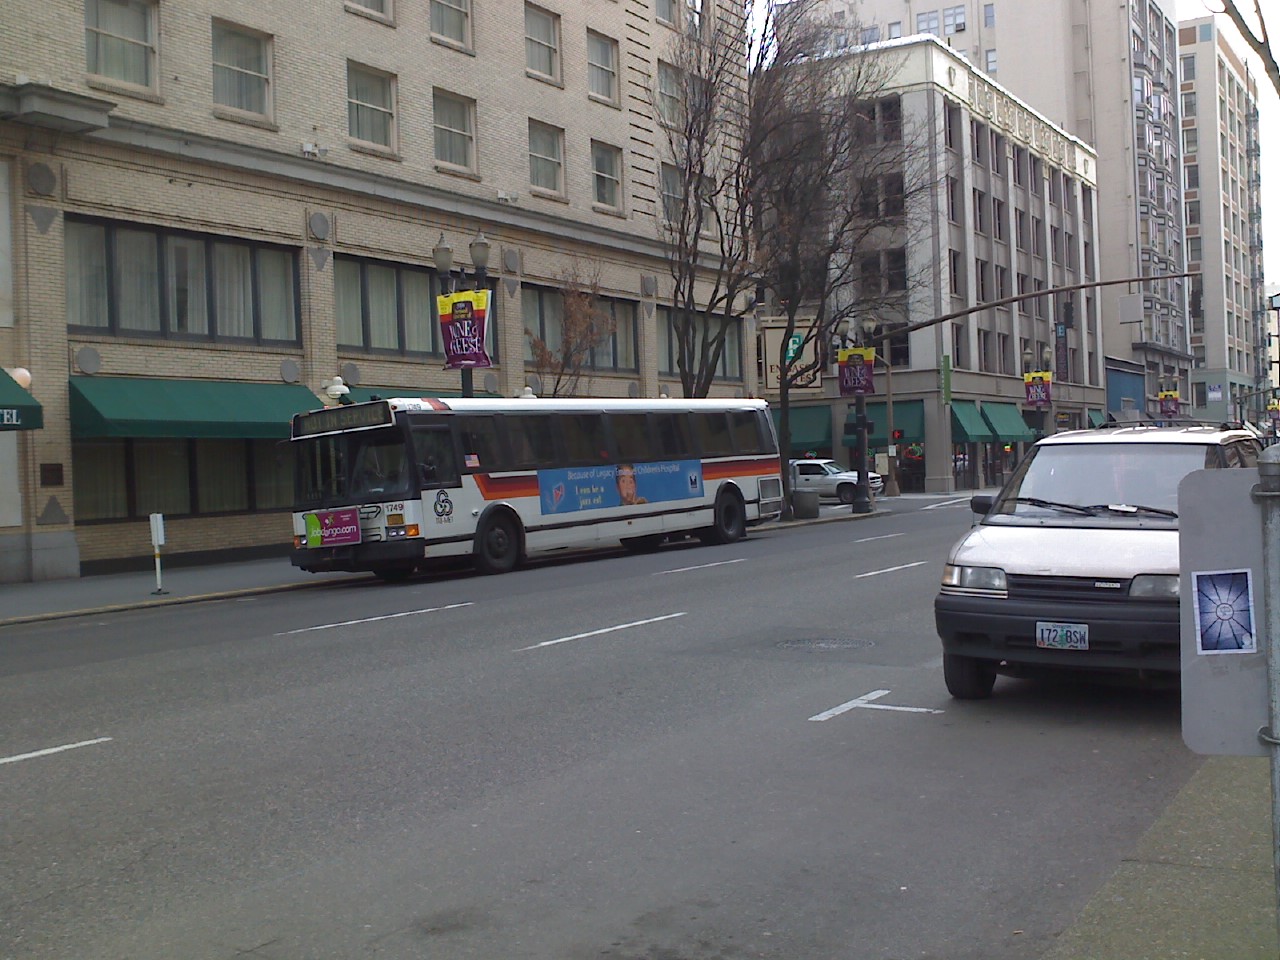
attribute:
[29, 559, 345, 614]
curb — concrete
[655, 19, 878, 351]
leaves — no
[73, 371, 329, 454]
awning — green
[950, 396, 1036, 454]
awnings — green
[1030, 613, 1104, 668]
plate — license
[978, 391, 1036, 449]
awning — green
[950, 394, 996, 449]
awning — green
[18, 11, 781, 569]
building — one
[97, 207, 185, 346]
window — one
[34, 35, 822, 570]
building — one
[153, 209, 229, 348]
window — one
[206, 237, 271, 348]
window — one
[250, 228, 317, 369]
window — one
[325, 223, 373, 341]
window — one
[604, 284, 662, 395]
window — one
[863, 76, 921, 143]
window — one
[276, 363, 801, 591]
bus — parked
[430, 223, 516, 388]
light — street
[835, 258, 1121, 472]
light — street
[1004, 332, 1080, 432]
light — street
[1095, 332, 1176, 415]
light — street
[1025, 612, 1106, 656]
plate — license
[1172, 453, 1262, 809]
sign — one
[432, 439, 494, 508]
flag — one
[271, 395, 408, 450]
display — electronic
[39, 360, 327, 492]
awning — one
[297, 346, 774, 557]
bus — transit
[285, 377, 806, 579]
bus — transit, parked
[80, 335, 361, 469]
awning — green, window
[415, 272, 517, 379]
flag — colorful, street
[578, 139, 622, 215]
windows — building, tan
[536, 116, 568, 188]
windows — tan, building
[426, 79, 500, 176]
windows — building, tan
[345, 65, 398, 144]
windows — tan, building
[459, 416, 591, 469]
windows — row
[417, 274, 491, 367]
signdisplay — window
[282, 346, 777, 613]
bus — light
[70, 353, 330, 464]
canopy — window display